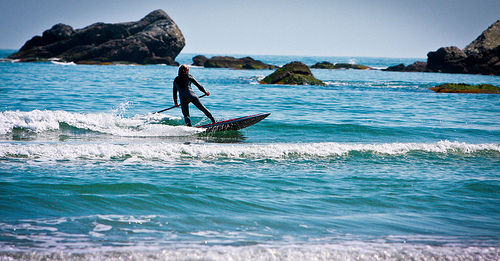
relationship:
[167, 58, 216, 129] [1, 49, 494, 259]
person in water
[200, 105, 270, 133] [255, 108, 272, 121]
surfboard has tip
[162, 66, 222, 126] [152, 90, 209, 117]
woman has paddle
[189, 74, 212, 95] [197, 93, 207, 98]
arm holds paddle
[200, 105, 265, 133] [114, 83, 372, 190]
surfboard on water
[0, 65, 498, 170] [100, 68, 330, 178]
woman on water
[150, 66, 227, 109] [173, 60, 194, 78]
woman has hair